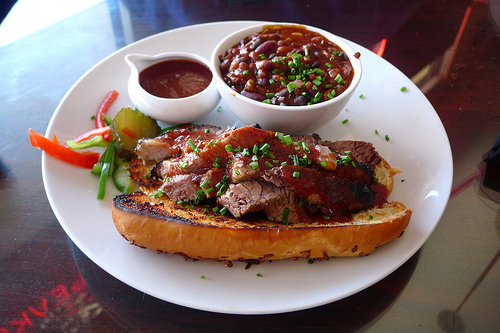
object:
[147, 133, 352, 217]
meat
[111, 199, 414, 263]
bread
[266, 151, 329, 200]
sauce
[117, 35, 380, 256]
food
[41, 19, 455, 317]
plate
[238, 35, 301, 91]
beans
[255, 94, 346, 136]
bowl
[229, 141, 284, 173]
parsley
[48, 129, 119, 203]
bell peppers